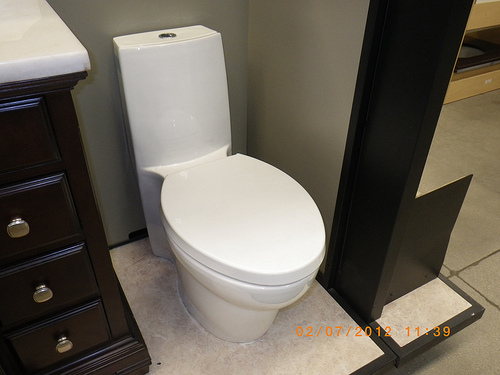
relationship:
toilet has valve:
[113, 23, 328, 347] [159, 31, 180, 40]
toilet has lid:
[113, 23, 328, 347] [160, 152, 327, 275]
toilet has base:
[113, 23, 328, 347] [143, 218, 328, 348]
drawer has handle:
[3, 172, 83, 257] [8, 213, 33, 240]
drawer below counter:
[3, 172, 83, 257] [1, 1, 92, 85]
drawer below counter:
[4, 242, 100, 331] [1, 1, 92, 85]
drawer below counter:
[7, 300, 113, 372] [1, 1, 92, 85]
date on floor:
[294, 321, 453, 339] [107, 229, 381, 373]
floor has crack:
[373, 88, 499, 373] [448, 247, 499, 312]